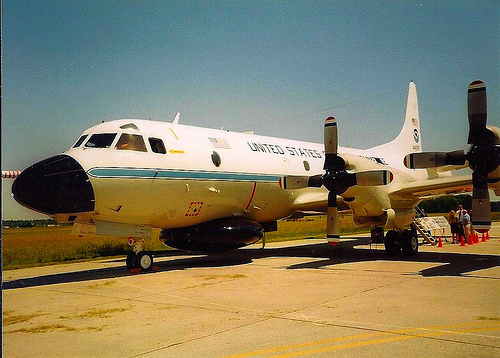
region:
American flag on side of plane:
[205, 130, 230, 150]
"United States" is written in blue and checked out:
[246, 140, 317, 155]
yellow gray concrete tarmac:
[5, 210, 490, 342]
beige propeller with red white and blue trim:
[275, 106, 390, 252]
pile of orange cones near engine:
[430, 225, 495, 250]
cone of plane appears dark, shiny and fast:
[6, 153, 103, 220]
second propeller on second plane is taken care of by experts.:
[400, 75, 495, 240]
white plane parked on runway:
[6, 75, 441, 265]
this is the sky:
[198, 10, 331, 90]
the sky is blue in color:
[213, 27, 305, 97]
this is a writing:
[242, 133, 324, 155]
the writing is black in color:
[239, 133, 280, 153]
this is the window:
[143, 137, 178, 154]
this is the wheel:
[128, 246, 169, 265]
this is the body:
[125, 124, 249, 191]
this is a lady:
[441, 199, 459, 241]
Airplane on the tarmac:
[11, 85, 498, 260]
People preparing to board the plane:
[441, 197, 481, 247]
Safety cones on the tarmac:
[431, 229, 493, 251]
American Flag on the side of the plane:
[202, 128, 238, 154]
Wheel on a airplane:
[118, 246, 161, 276]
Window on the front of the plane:
[70, 131, 170, 158]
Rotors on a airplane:
[267, 111, 394, 253]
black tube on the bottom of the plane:
[160, 213, 277, 261]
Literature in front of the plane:
[409, 192, 447, 251]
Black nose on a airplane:
[15, 149, 87, 235]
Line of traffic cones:
[458, 233, 492, 248]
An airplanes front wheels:
[110, 227, 166, 277]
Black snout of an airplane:
[4, 150, 97, 217]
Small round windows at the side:
[205, 145, 239, 171]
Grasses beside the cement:
[8, 228, 104, 280]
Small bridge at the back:
[413, 215, 442, 248]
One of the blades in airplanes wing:
[310, 105, 357, 177]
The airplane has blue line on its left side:
[1, 109, 291, 199]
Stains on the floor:
[1, 277, 145, 357]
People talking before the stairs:
[414, 200, 477, 246]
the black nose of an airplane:
[10, 151, 95, 220]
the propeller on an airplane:
[277, 114, 393, 262]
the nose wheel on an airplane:
[121, 245, 151, 275]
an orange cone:
[432, 232, 442, 247]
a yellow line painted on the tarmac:
[218, 316, 496, 357]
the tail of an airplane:
[382, 78, 424, 204]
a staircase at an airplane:
[413, 207, 442, 247]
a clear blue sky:
[1, 2, 497, 167]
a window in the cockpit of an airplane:
[82, 127, 117, 151]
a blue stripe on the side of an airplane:
[85, 159, 285, 185]